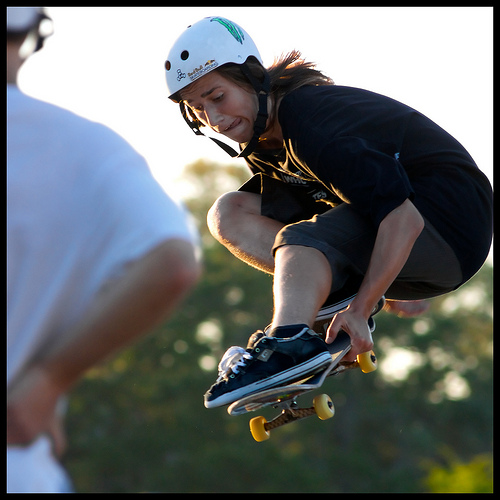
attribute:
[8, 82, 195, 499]
shirt —  white 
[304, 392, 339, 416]
wheels — yellow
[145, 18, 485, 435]
skateboarder — air 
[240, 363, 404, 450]
wheels — yellow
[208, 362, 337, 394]
sole — white 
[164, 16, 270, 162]
helmet — white, skate boarding helmet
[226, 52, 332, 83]
hair —  Brown 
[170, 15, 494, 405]
man — young,  young 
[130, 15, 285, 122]
helmet — white skateboarding 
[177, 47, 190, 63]
hole — black 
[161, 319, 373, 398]
skate shoes — black skate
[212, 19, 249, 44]
design —  Green 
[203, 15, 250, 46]
green logo — green 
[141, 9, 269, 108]
helmet — side 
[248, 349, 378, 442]
wheels — yellow 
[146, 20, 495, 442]
skater — air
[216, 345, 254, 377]
laces — white  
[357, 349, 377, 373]
wheel — yellow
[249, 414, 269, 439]
wheel — yellow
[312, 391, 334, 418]
wheel — yellow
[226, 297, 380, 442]
skateboard — black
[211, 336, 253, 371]
shoelaces —  White 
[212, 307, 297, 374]
shoelaces — white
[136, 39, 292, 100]
helmet — white , green design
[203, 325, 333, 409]
shoe — skate   ,  Black , black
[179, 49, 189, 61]
hole — black 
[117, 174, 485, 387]
trees —  background.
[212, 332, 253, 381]
laces — white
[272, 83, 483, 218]
top — black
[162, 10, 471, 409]
man —  Young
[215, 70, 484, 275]
shirt —  black 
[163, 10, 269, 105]
helmet — white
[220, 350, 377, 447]
wheels — yellow 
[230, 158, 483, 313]
shorts — dark 